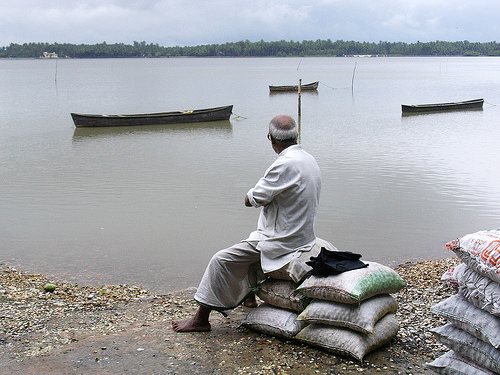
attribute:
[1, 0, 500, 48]
sky — grey, cloudy, blue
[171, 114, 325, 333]
man — sitting, barefoot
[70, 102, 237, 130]
boat — brown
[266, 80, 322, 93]
boat — brown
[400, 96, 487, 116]
boat — brown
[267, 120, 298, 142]
hair — white, grey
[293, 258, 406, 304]
sack — white, stacked, potatoes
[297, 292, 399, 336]
sack — white, stacked, potatoes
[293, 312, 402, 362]
sack — white, stacked, potatoes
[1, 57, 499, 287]
lake — brown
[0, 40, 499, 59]
trees — green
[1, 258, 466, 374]
beach — stones, rocky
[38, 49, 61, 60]
home — large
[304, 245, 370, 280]
item — black, umbrella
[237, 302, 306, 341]
sack — potatoes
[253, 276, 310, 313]
sack — potatoes